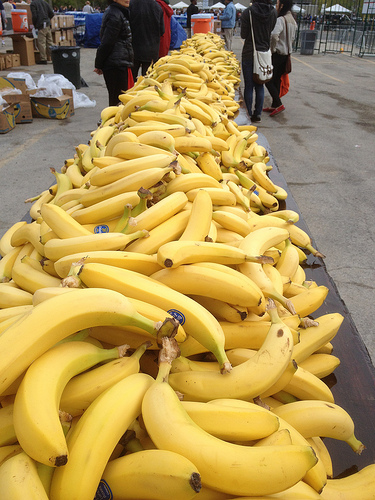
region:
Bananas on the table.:
[136, 75, 211, 279]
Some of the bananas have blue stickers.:
[163, 306, 188, 332]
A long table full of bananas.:
[149, 39, 241, 252]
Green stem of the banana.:
[214, 343, 236, 370]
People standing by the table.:
[101, 8, 291, 91]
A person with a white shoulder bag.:
[245, 9, 276, 88]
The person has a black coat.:
[95, 11, 131, 70]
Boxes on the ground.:
[11, 78, 76, 129]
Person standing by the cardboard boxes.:
[27, 4, 55, 62]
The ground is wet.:
[322, 88, 370, 114]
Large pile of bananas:
[2, 28, 326, 480]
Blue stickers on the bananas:
[164, 305, 191, 331]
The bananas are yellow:
[7, 36, 341, 495]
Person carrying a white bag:
[239, 2, 273, 124]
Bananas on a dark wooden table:
[7, 30, 370, 496]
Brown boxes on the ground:
[2, 69, 75, 133]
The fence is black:
[290, 0, 372, 57]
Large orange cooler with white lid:
[9, 9, 32, 33]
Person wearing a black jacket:
[91, 0, 137, 80]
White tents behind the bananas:
[164, 2, 354, 17]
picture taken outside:
[4, 7, 373, 498]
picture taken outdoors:
[5, 5, 370, 493]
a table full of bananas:
[162, 66, 264, 427]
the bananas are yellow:
[113, 69, 226, 412]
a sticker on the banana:
[96, 225, 109, 233]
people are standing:
[96, 9, 301, 125]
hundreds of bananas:
[103, 50, 232, 474]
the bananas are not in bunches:
[115, 93, 246, 493]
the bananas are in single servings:
[117, 140, 287, 425]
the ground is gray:
[308, 77, 372, 238]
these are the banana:
[68, 50, 230, 484]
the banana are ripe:
[40, 327, 279, 497]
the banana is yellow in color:
[162, 430, 200, 451]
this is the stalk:
[130, 307, 166, 336]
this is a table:
[338, 365, 366, 396]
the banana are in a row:
[91, 67, 243, 371]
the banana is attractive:
[199, 272, 230, 296]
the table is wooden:
[338, 353, 365, 398]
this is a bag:
[251, 49, 274, 81]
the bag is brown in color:
[252, 47, 276, 85]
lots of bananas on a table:
[32, 144, 291, 335]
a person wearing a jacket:
[87, 9, 164, 99]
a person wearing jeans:
[245, 42, 283, 124]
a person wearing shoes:
[261, 90, 297, 121]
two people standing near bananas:
[235, 0, 329, 111]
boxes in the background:
[6, 45, 99, 132]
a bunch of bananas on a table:
[56, 33, 348, 395]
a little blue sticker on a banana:
[151, 295, 201, 332]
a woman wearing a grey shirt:
[265, 3, 341, 56]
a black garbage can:
[39, 31, 102, 101]